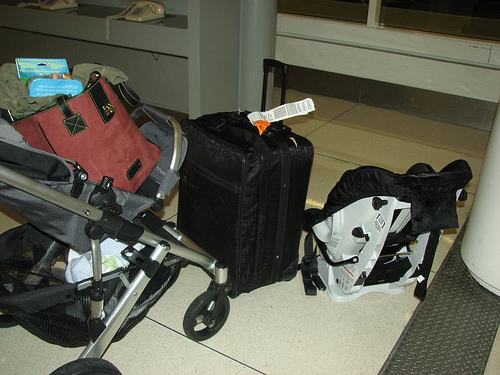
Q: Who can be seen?
A: No one.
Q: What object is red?
A: A bag.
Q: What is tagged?
A: Luggage.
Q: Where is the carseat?
A: On the ground.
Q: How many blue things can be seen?
A: Two.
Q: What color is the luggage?
A: Black.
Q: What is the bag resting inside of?
A: A stroller.